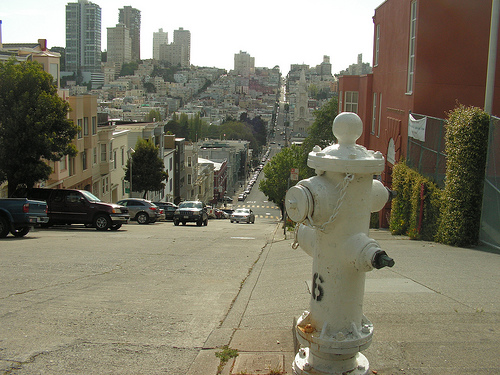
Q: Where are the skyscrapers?
A: On the back left.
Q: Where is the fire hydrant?
A: On the sidewalk.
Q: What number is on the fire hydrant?
A: 6.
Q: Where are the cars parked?
A: On the side of the street.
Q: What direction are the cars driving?
A: Up the hill.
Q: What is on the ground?
A: Cement.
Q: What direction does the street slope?
A: Downward.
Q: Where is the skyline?
A: In the distance.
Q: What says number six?
A: Hydrant.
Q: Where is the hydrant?
A: Corner.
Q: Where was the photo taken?
A: Hill.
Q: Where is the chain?
A: Hanging on hydrant.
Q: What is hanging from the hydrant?
A: Chain.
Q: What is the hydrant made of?
A: Metal.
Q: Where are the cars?
A: Street.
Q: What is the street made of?
A: Cement.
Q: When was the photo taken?
A: Morning.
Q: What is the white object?
A: Fire hydrant.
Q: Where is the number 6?
A: Fire hydrant.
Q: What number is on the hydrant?
A: 6.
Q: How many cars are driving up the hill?
A: 2.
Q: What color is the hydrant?
A: White.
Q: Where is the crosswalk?
A: The bottom of the hill.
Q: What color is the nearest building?
A: Red.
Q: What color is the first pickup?
A: Blue.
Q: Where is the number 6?
A: On the hydrant.